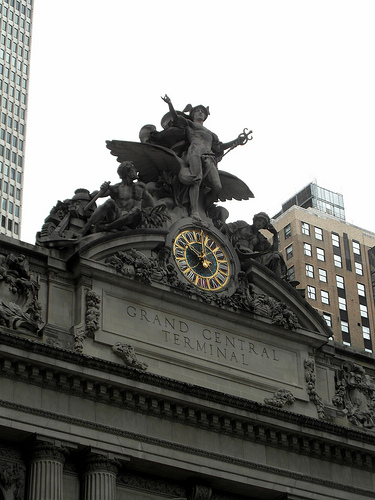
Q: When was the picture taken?
A: Daytime.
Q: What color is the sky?
A: White.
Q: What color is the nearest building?
A: Gray.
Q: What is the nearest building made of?
A: Stone.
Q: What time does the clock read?
A: 10:00.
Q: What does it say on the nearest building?
A: GRAND CENTRAL TERMINAL.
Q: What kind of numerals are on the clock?
A: Roman.